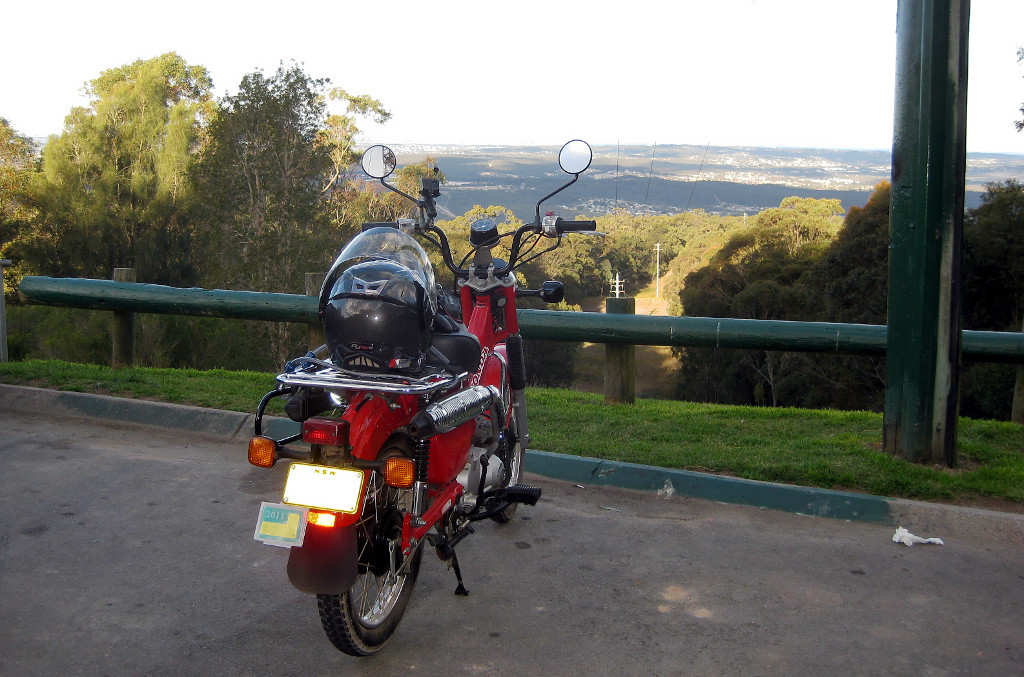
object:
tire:
[317, 435, 426, 656]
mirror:
[559, 140, 594, 175]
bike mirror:
[361, 145, 397, 179]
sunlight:
[657, 586, 713, 619]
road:
[0, 409, 1024, 673]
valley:
[440, 140, 891, 219]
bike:
[247, 140, 598, 659]